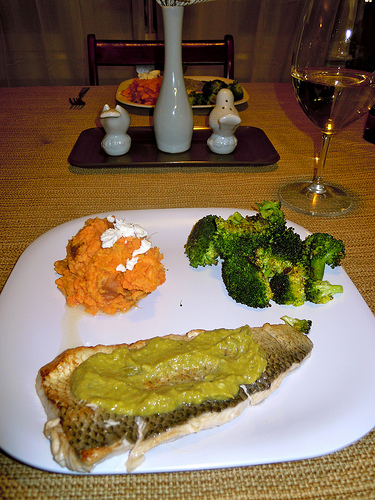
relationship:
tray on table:
[66, 123, 280, 169] [3, 88, 372, 206]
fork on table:
[63, 84, 91, 105] [2, 84, 373, 499]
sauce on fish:
[74, 323, 265, 414] [31, 320, 316, 475]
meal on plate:
[33, 194, 355, 477] [1, 198, 373, 480]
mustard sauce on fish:
[72, 324, 271, 415] [31, 320, 316, 475]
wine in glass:
[290, 69, 371, 129] [279, 3, 374, 218]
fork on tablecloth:
[66, 85, 91, 108] [7, 88, 371, 309]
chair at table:
[72, 32, 244, 82] [4, 70, 373, 203]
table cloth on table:
[19, 132, 57, 214] [9, 84, 373, 327]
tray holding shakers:
[65, 106, 305, 186] [90, 79, 241, 159]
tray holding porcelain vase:
[65, 106, 305, 186] [153, 5, 194, 155]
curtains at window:
[0, 5, 339, 83] [0, 4, 308, 85]